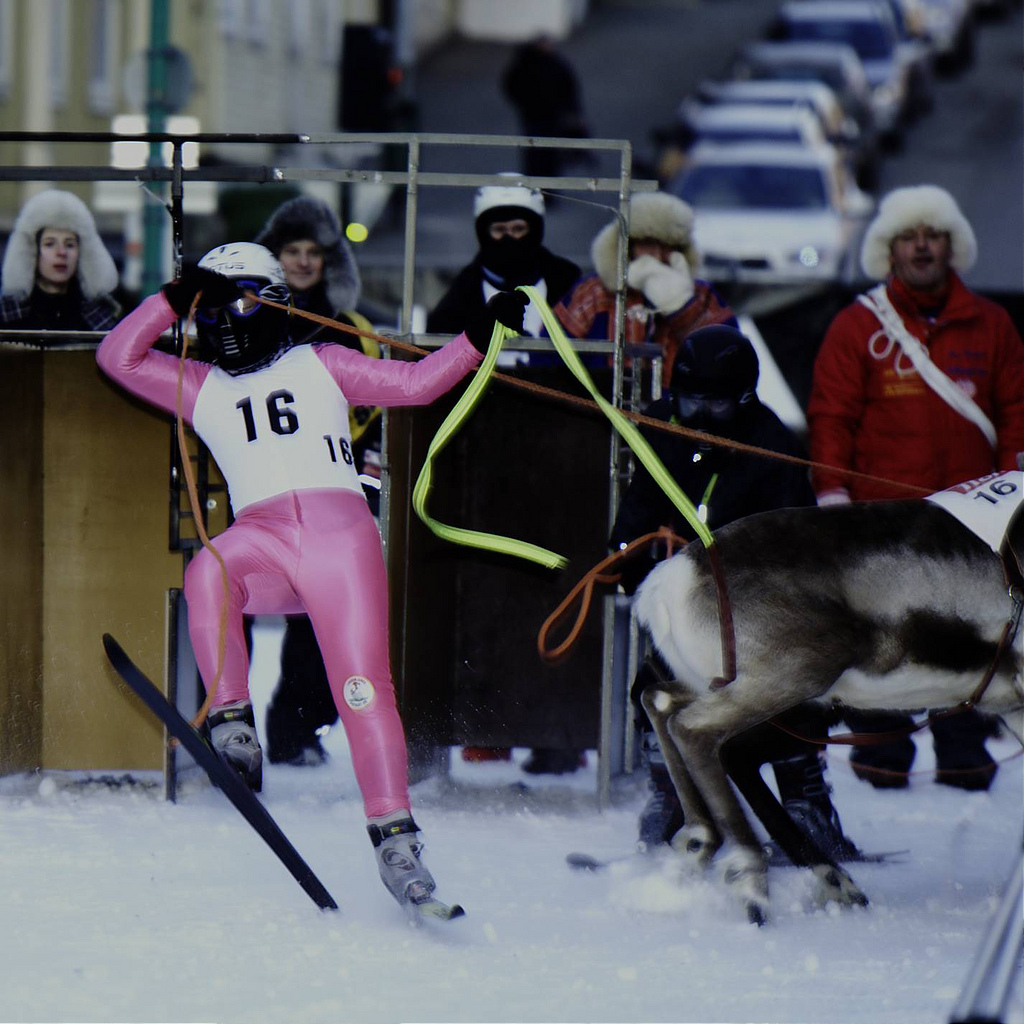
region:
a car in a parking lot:
[650, 86, 846, 173]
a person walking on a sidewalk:
[437, 172, 571, 334]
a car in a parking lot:
[921, 2, 982, 66]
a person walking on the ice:
[50, 191, 537, 900]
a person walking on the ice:
[614, 315, 865, 881]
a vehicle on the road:
[730, 62, 852, 138]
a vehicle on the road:
[678, 85, 830, 150]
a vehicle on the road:
[773, 75, 857, 137]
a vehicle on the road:
[777, 75, 853, 173]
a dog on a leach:
[652, 470, 1017, 917]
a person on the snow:
[11, 215, 558, 1016]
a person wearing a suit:
[128, 247, 388, 791]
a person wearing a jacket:
[772, 171, 1000, 525]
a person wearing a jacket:
[547, 215, 778, 516]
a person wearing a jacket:
[444, 189, 563, 349]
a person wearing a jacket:
[242, 221, 359, 338]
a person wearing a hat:
[544, 116, 696, 350]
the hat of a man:
[842, 177, 964, 250]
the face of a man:
[892, 215, 950, 288]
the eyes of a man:
[886, 221, 964, 241]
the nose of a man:
[886, 227, 941, 270]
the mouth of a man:
[895, 247, 950, 270]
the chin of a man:
[892, 265, 962, 303]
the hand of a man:
[804, 476, 874, 519]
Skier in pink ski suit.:
[118, 236, 523, 926]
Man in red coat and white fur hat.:
[810, 172, 1016, 506]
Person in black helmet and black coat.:
[611, 328, 820, 515]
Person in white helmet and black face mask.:
[447, 173, 580, 338]